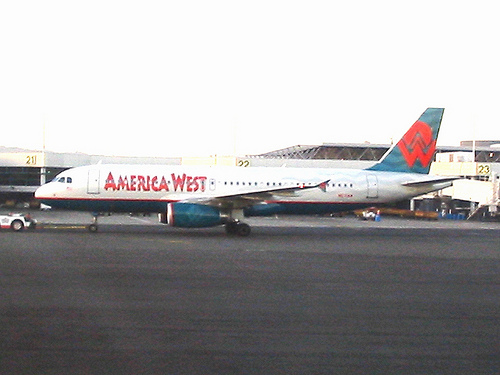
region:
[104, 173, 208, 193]
brand name of the airline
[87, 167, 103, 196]
front door of the airplane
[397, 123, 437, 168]
logo of the airline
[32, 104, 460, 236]
small passenger jet on the tarmac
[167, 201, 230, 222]
jet engine hanging on wing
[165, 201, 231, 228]
blue and silver jet engine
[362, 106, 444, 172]
tail fin of the aircraft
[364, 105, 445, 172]
tail fin of the airplane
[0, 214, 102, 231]
ground equipment pulling the plane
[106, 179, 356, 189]
a row passenger windows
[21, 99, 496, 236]
America West jetliner on the tarmac at an airport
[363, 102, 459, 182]
large blue and red tail of the jetliner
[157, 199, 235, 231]
large jet engine on the aircraft's wing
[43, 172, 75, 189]
cockpit windows of the airliner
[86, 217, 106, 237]
front landing gear of the airliner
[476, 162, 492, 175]
black 23 to indicate the gate number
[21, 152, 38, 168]
black 21 indicating the gate number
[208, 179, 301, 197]
row of small windows on the aircraft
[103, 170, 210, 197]
red America West logo on the side of the airplane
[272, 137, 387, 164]
metal roof of the airport terminal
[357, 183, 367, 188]
part of a plane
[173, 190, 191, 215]
part of a wheel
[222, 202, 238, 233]
edge of a wheel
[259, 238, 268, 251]
part of a wheel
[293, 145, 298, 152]
edge of a plane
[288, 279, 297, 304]
part of a plane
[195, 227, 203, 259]
part of a wheel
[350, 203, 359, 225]
part of a plane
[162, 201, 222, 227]
blue engine on the side of the plane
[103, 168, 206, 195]
the words america west in red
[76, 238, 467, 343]
the airplane tarmac is black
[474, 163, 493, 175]
the number 23 is on the side of building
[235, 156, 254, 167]
the number 22 on the side of building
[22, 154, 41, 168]
the number 21 on the side of building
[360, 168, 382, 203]
the back door of the airplane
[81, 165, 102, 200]
the front door of the airplane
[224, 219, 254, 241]
two black wheels on the middle of the plane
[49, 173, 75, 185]
the small windows on the front of plane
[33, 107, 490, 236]
red white and blue plane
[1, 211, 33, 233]
white car on runway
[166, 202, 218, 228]
booster jet on plane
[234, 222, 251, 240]
black tire on plane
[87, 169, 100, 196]
white door on plane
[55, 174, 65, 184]
wind shield on plane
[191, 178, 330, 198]
white wing on plane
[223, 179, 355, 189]
windows on side of plane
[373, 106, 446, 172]
tail on wing of plane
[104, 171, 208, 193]
red writing on plane